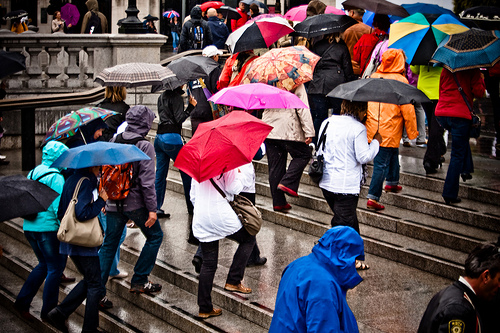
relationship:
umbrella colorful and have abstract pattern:
[172, 110, 274, 185] [158, 125, 253, 236]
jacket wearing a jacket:
[268, 225, 368, 333] [283, 226, 374, 333]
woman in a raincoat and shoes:
[365, 48, 423, 210] [365, 178, 403, 233]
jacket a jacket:
[268, 225, 368, 333] [264, 223, 389, 333]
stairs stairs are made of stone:
[0, 216, 274, 333] [222, 289, 279, 333]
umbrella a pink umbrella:
[207, 83, 308, 110] [243, 100, 273, 138]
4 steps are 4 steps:
[145, 130, 498, 283] [132, 117, 498, 280]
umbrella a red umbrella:
[172, 110, 274, 185] [172, 114, 287, 239]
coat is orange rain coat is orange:
[365, 49, 419, 148] [365, 49, 419, 148]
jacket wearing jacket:
[268, 225, 368, 333] [318, 113, 377, 196]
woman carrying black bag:
[316, 98, 383, 270] [302, 122, 328, 179]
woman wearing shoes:
[363, 48, 422, 215] [384, 185, 403, 194]